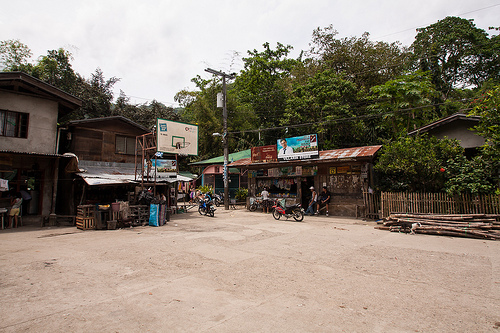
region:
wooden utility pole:
[205, 67, 239, 209]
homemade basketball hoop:
[133, 118, 198, 227]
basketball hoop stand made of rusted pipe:
[130, 130, 156, 228]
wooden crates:
[75, 203, 96, 230]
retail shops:
[188, 135, 303, 211]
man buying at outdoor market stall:
[246, 167, 297, 215]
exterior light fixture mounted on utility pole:
[211, 131, 226, 140]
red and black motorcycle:
[271, 197, 306, 220]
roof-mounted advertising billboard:
[136, 158, 176, 181]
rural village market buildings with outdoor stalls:
[1, 0, 498, 332]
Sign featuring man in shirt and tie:
[275, 135, 317, 160]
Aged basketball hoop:
[135, 118, 196, 224]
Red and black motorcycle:
[270, 199, 304, 221]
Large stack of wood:
[377, 213, 498, 238]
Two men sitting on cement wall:
[304, 184, 331, 216]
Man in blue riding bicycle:
[196, 189, 216, 218]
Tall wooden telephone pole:
[203, 66, 237, 209]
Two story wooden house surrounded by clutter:
[63, 113, 171, 230]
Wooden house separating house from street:
[360, 190, 499, 220]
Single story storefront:
[233, 145, 383, 217]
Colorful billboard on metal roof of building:
[277, 132, 319, 165]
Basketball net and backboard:
[149, 115, 199, 157]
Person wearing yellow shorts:
[2, 190, 33, 230]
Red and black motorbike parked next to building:
[269, 199, 306, 229]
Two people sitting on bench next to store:
[305, 185, 339, 222]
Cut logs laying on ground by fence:
[375, 210, 498, 246]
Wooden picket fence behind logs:
[374, 195, 499, 230]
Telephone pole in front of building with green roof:
[193, 65, 242, 215]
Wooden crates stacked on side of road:
[77, 204, 100, 232]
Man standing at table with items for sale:
[245, 182, 300, 212]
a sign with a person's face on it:
[276, 132, 321, 159]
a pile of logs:
[373, 208, 498, 243]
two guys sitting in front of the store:
[302, 183, 332, 215]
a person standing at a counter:
[254, 185, 271, 212]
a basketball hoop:
[168, 133, 190, 160]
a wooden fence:
[361, 188, 496, 224]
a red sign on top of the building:
[248, 143, 277, 163]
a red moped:
[270, 194, 306, 224]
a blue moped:
[198, 188, 218, 216]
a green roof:
[186, 145, 256, 163]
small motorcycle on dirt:
[268, 188, 327, 220]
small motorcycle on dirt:
[206, 196, 223, 216]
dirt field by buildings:
[25, 206, 457, 331]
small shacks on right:
[219, 148, 372, 232]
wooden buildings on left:
[9, 84, 169, 184]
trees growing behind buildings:
[216, 39, 477, 174]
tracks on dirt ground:
[82, 246, 229, 326]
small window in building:
[0, 102, 26, 124]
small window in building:
[109, 137, 146, 159]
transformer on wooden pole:
[213, 87, 223, 109]